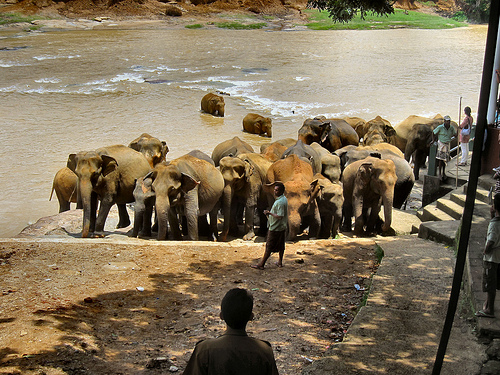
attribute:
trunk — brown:
[76, 175, 93, 236]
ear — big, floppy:
[65, 152, 77, 172]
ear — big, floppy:
[98, 151, 118, 186]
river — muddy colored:
[0, 24, 484, 234]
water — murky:
[0, 22, 482, 234]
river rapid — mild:
[1, 52, 370, 120]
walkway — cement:
[310, 201, 484, 372]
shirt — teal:
[430, 121, 459, 143]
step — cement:
[419, 201, 457, 224]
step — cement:
[435, 196, 465, 220]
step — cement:
[450, 190, 485, 210]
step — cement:
[463, 182, 484, 202]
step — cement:
[478, 173, 485, 183]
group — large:
[47, 110, 459, 242]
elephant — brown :
[239, 110, 274, 137]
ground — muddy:
[1, 239, 381, 372]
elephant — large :
[65, 149, 167, 229]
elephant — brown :
[341, 157, 401, 233]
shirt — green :
[431, 127, 461, 147]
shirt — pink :
[462, 115, 476, 131]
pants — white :
[453, 130, 473, 162]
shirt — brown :
[179, 327, 282, 373]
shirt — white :
[264, 198, 290, 234]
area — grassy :
[299, 10, 470, 33]